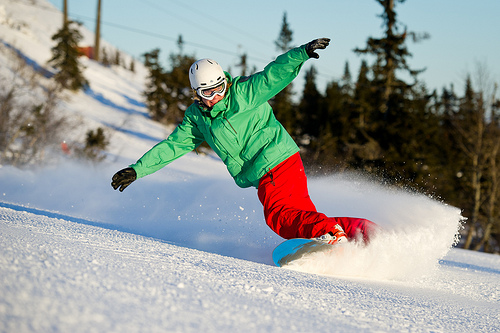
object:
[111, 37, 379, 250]
person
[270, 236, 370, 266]
snowboard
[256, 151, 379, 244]
pants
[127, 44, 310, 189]
jacket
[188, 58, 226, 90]
helmet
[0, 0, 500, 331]
snow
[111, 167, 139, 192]
glove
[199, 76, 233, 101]
goggles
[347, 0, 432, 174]
tree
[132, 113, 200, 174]
arm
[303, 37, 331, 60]
hand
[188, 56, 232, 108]
head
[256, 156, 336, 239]
leg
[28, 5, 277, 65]
wire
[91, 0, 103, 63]
pole